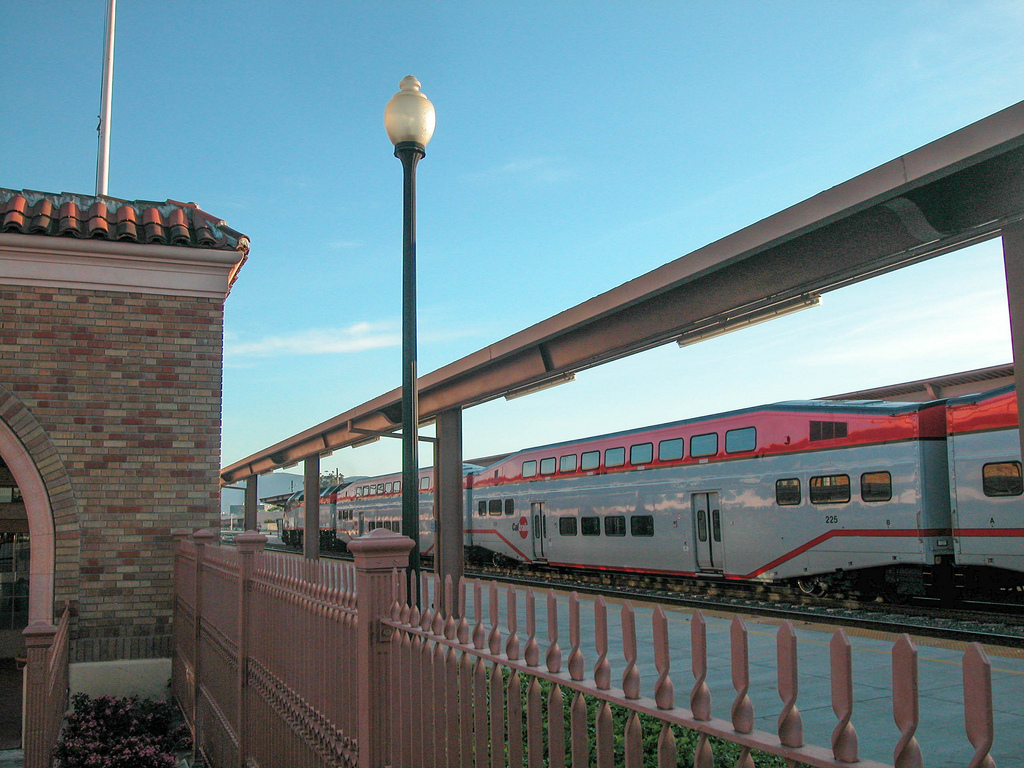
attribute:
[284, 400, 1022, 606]
train — long, gray, red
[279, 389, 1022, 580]
train — red, gray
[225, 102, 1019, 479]
overhang — metal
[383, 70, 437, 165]
bulb — white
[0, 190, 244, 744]
building — brick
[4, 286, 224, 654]
bricks — gray, red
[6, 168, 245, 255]
roof — tiled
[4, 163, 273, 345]
roof — red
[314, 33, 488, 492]
post — black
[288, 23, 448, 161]
bulb — white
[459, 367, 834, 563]
train — red, silver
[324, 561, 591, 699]
fence — pink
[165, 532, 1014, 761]
fence — metal, pink